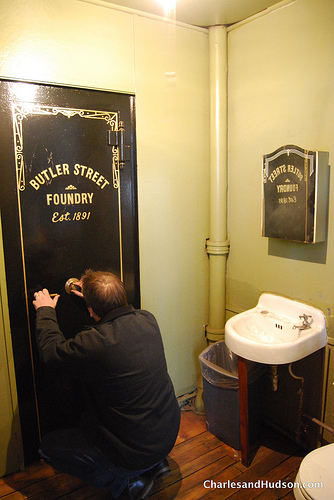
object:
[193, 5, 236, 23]
ceiling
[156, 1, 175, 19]
light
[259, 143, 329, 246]
cabinet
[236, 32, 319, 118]
wall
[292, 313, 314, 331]
faucet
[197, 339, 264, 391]
bag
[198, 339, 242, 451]
trash can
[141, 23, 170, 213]
wall safe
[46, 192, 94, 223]
letters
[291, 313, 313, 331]
water faucet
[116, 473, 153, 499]
shoe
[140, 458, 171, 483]
shoe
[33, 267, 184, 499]
man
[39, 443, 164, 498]
jeans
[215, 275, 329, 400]
bathroom sink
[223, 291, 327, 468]
bathroom sink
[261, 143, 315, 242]
mirror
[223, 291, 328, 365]
sink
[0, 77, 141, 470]
safe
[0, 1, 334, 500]
bathroom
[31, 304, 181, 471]
jacket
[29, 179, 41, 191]
letter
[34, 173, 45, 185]
letter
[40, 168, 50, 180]
letter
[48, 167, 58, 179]
letter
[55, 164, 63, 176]
letter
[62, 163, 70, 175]
letter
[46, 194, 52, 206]
letter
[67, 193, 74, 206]
letter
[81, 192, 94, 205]
letter